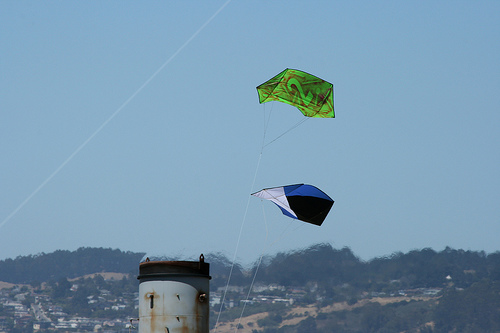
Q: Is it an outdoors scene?
A: Yes, it is outdoors.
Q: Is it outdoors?
A: Yes, it is outdoors.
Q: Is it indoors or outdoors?
A: It is outdoors.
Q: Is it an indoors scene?
A: No, it is outdoors.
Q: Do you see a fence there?
A: No, there are no fences.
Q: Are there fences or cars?
A: No, there are no fences or cars.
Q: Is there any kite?
A: Yes, there is a kite.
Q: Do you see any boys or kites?
A: Yes, there is a kite.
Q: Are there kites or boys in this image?
A: Yes, there is a kite.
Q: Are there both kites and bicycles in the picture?
A: No, there is a kite but no bikes.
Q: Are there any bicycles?
A: No, there are no bicycles.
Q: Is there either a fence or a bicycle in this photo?
A: No, there are no bicycles or fences.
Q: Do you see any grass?
A: Yes, there is grass.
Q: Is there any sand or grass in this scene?
A: Yes, there is grass.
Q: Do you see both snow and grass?
A: No, there is grass but no snow.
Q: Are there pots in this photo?
A: No, there are no pots.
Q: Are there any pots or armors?
A: No, there are no pots or armors.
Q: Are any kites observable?
A: Yes, there is a kite.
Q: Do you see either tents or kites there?
A: Yes, there is a kite.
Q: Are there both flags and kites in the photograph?
A: No, there is a kite but no flags.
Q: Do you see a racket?
A: No, there are no rackets.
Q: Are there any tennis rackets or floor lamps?
A: No, there are no tennis rackets or floor lamps.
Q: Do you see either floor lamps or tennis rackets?
A: No, there are no tennis rackets or floor lamps.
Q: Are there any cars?
A: No, there are no cars.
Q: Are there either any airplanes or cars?
A: No, there are no cars or airplanes.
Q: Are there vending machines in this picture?
A: No, there are no vending machines.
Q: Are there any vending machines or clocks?
A: No, there are no vending machines or clocks.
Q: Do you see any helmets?
A: No, there are no helmets.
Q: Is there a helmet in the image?
A: No, there are no helmets.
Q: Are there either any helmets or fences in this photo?
A: No, there are no helmets or fences.